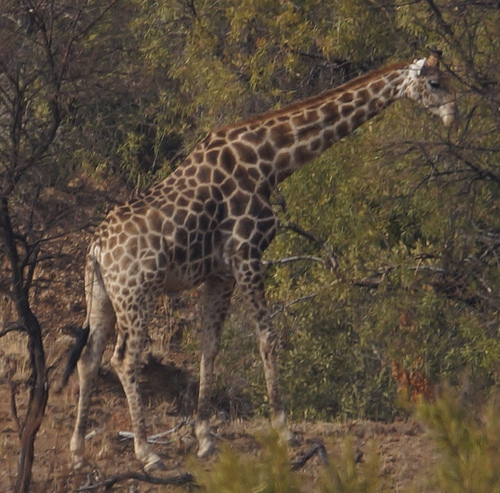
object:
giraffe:
[49, 36, 460, 487]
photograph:
[0, 0, 499, 491]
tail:
[48, 256, 107, 402]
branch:
[103, 409, 195, 452]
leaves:
[389, 335, 409, 360]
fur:
[125, 188, 205, 263]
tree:
[76, 0, 499, 341]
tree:
[1, 0, 208, 492]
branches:
[248, 204, 337, 274]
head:
[371, 33, 467, 148]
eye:
[415, 76, 445, 98]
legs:
[183, 270, 240, 468]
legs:
[232, 256, 312, 466]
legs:
[105, 258, 192, 485]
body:
[64, 125, 303, 484]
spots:
[158, 218, 174, 246]